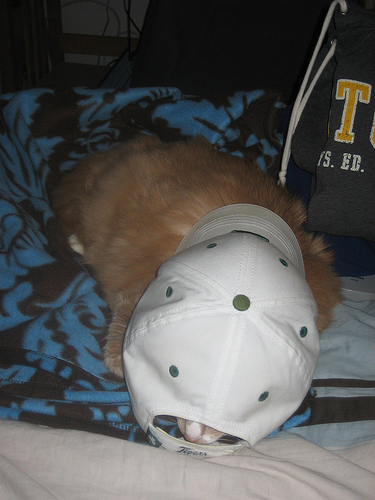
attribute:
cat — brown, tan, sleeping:
[54, 132, 345, 446]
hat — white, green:
[121, 199, 323, 459]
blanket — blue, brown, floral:
[1, 84, 316, 443]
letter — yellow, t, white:
[333, 77, 372, 145]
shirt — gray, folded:
[282, 2, 374, 239]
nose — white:
[179, 419, 226, 446]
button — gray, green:
[232, 293, 252, 312]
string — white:
[273, 0, 348, 186]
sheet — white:
[1, 424, 374, 499]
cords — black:
[99, 3, 141, 85]